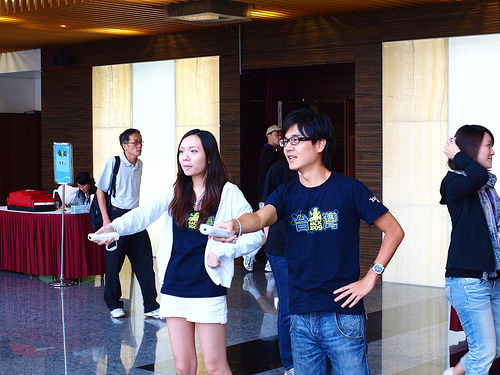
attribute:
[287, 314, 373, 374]
jeans — pair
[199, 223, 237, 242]
remotes — held, white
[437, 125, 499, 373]
woman — scratching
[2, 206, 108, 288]
table — red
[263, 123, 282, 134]
cap — beige, brown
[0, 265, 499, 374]
floor — gray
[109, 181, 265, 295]
jacket — white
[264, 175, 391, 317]
shirt — blue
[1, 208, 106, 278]
tablecloth — red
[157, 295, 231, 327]
shorts — white